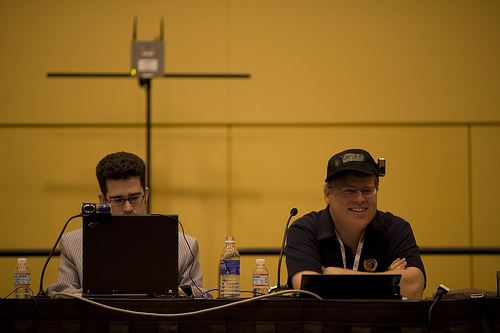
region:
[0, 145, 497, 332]
Two people sitting at a table.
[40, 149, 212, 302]
A man with an open laptop.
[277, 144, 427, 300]
A man sitting with his arms crossed.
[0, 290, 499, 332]
A black table.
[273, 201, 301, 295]
A microphone.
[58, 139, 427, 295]
two men sitting at a table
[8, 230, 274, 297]
plastic water bottles on the table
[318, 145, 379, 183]
black hat man is wearing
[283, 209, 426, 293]
black shirt man is wearing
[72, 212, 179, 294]
open black laptop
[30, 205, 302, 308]
two microphones on the table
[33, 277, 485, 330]
cords on the table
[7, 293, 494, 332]
black cloth on the table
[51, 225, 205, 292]
beige jacket man is wearing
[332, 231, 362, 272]
lanyard around man's neck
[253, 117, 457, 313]
a man smiling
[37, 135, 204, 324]
a man working at a laptop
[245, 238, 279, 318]
a closed bottle of water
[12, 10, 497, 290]
a yellow wall in the background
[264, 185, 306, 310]
a microphone on a table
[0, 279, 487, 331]
a table full of electronics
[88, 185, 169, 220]
a pair of glasses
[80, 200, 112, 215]
a computer web cam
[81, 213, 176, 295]
an open laptop computer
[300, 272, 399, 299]
an open laptop computer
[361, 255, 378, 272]
a Firefox browser logo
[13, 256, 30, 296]
a clear water bottle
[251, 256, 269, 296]
a clear water bottle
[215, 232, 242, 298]
water bottle with blue lable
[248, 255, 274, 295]
small water bottle with cap on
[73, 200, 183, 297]
back of laptop computer monitor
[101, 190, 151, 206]
eye glasses on man's face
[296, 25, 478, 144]
yellow colored wall behind the men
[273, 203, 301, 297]
microphone on table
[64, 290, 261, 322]
power cable along front of table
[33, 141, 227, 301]
man in striped coat working on computer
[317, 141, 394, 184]
black hat with rectangular device attached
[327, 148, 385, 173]
The hat the man is wearing.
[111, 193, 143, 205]
The eyeglasses the man on the left is wearing.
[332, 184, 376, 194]
The glasses the man on the right is wearing.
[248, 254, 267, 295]
The small bottle of water.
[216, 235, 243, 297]
water bottle on table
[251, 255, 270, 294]
water bottle on table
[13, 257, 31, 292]
water bottle on table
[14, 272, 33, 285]
label on water bottle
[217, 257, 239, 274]
label on water bottle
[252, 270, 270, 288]
label on water bottle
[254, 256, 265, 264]
white lid on bottle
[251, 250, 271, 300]
bottle on a table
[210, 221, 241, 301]
bottle on a table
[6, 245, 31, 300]
bottle on a table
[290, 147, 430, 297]
man wearing a hat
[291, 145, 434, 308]
man wearing black shirt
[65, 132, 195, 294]
man wearing pair of eyeglasses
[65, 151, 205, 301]
man looking at computer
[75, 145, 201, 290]
man wearing a suite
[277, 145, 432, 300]
man sitting at a table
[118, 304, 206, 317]
cord on a table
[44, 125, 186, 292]
man sitting behind a laptop computer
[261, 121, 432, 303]
man with hat on smiling